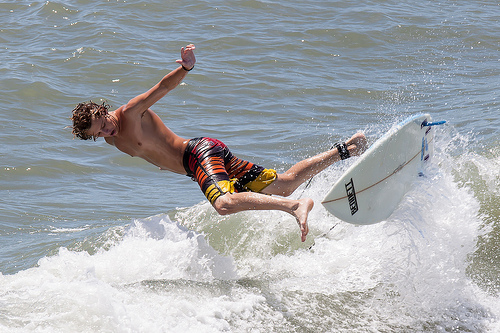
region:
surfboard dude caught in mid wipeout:
[61, 35, 453, 250]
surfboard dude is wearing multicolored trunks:
[181, 131, 281, 210]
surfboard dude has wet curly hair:
[68, 94, 117, 142]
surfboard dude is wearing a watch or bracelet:
[174, 54, 199, 77]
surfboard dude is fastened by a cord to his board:
[295, 108, 449, 210]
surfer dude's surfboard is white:
[316, 105, 451, 229]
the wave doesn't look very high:
[2, 127, 497, 329]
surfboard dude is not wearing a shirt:
[67, 40, 375, 245]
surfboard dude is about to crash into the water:
[66, 37, 376, 249]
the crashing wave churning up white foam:
[2, 213, 494, 329]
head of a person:
[63, 85, 111, 139]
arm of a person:
[133, 28, 191, 113]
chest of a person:
[119, 128, 150, 165]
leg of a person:
[212, 166, 313, 233]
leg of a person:
[280, 102, 365, 182]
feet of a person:
[297, 181, 327, 228]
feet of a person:
[336, 122, 378, 176]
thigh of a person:
[196, 139, 237, 204]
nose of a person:
[102, 125, 117, 140]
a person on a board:
[63, 8, 480, 266]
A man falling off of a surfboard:
[69, 43, 439, 242]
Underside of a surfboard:
[324, 115, 440, 225]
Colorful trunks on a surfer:
[182, 134, 275, 203]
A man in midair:
[68, 43, 312, 239]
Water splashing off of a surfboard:
[341, 128, 492, 320]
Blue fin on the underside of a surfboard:
[422, 117, 447, 128]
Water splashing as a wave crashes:
[5, 220, 228, 330]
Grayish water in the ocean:
[0, 5, 493, 142]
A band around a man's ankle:
[332, 137, 348, 157]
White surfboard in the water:
[322, 117, 446, 227]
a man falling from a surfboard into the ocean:
[73, 41, 366, 243]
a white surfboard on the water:
[319, 111, 434, 224]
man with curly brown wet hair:
[70, 98, 119, 143]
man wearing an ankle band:
[333, 140, 350, 159]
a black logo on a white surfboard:
[345, 178, 359, 214]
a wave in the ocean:
[0, 120, 499, 329]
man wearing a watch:
[180, 63, 195, 73]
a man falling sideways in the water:
[69, 43, 366, 243]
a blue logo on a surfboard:
[418, 133, 430, 158]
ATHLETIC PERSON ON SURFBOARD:
[62, 40, 444, 242]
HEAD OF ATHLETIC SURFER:
[66, 100, 118, 142]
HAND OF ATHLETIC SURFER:
[171, 43, 205, 68]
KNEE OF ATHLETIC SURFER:
[206, 192, 243, 217]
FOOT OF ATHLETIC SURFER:
[340, 124, 372, 154]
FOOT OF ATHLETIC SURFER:
[285, 198, 317, 235]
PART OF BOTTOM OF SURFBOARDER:
[372, 153, 411, 203]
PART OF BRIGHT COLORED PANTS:
[188, 143, 222, 175]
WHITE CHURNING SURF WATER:
[48, 275, 108, 332]